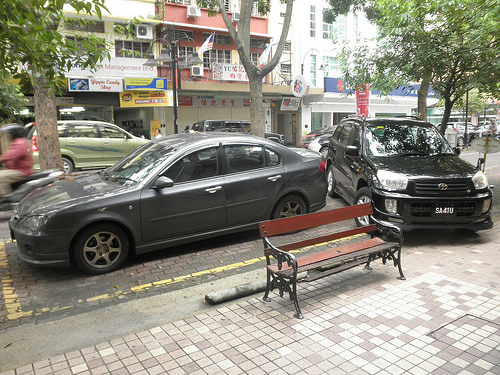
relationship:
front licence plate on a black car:
[372, 169, 434, 279] [324, 117, 495, 236]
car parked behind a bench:
[24, 129, 322, 266] [258, 202, 402, 307]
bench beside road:
[256, 197, 410, 320] [1, 113, 492, 198]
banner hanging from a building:
[351, 80, 372, 117] [172, 50, 181, 70]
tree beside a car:
[202, 0, 309, 142] [393, 113, 457, 143]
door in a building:
[272, 111, 286, 141] [0, 0, 499, 142]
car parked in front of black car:
[9, 130, 328, 274] [24, 129, 322, 266]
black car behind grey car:
[324, 117, 491, 239] [9, 132, 326, 274]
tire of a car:
[75, 221, 130, 278] [198, 151, 226, 282]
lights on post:
[144, 48, 203, 67] [169, 48, 179, 132]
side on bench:
[259, 232, 302, 320] [256, 197, 410, 320]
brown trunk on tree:
[31, 74, 63, 171] [5, 2, 102, 192]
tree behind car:
[0, 1, 98, 168] [7, 112, 328, 276]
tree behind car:
[202, 0, 309, 142] [7, 112, 328, 276]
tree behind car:
[365, 4, 499, 158] [7, 112, 328, 276]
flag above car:
[199, 34, 214, 54] [192, 120, 286, 145]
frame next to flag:
[156, 7, 265, 56] [206, 31, 214, 60]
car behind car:
[27, 120, 150, 174] [8, 132, 335, 280]